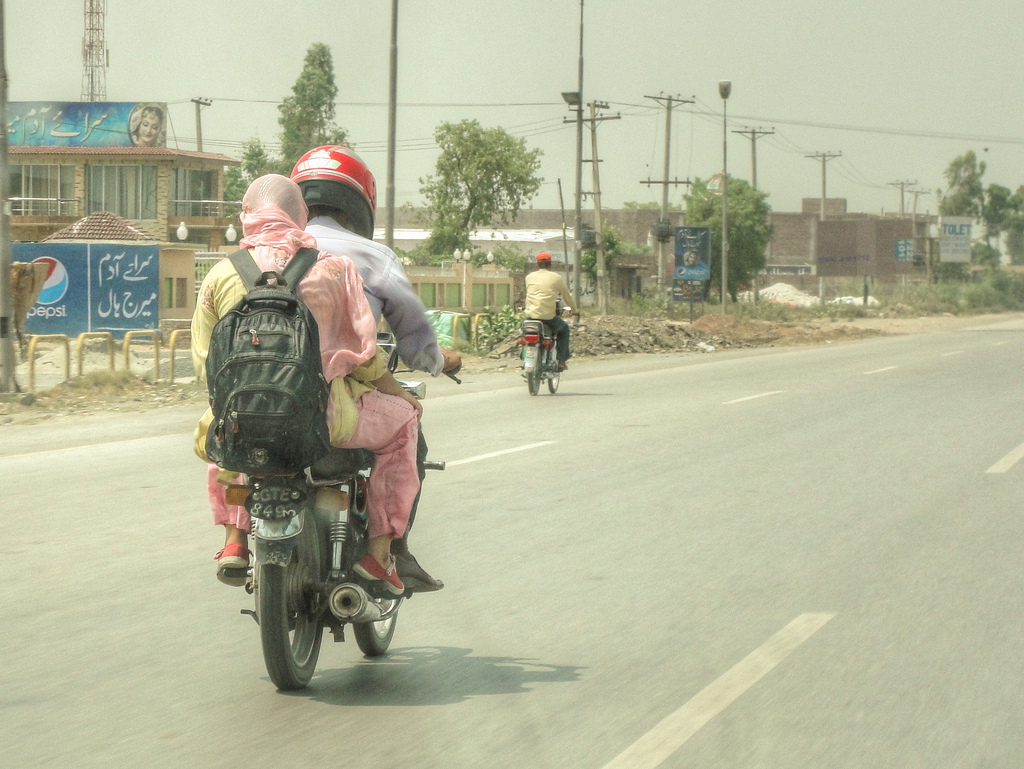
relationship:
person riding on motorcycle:
[285, 121, 471, 355] [203, 411, 499, 713]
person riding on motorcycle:
[166, 165, 434, 634] [203, 411, 499, 713]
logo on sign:
[21, 250, 72, 321] [11, 237, 158, 330]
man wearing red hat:
[472, 221, 619, 409] [523, 248, 568, 267]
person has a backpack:
[191, 173, 421, 595] [142, 270, 402, 508]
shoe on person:
[358, 558, 406, 593] [191, 173, 421, 595]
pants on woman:
[311, 372, 423, 537] [179, 168, 450, 627]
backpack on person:
[200, 228, 350, 484] [191, 173, 421, 595]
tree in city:
[418, 119, 527, 250] [13, 12, 1009, 766]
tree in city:
[280, 40, 358, 177] [13, 12, 1009, 766]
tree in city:
[229, 140, 294, 186] [13, 12, 1009, 766]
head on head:
[288, 146, 375, 241] [286, 145, 374, 219]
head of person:
[286, 145, 374, 219] [290, 145, 457, 596]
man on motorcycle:
[525, 253, 579, 371] [506, 312, 568, 395]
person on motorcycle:
[191, 173, 421, 595] [232, 450, 452, 685]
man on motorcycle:
[294, 144, 468, 378] [232, 450, 452, 685]